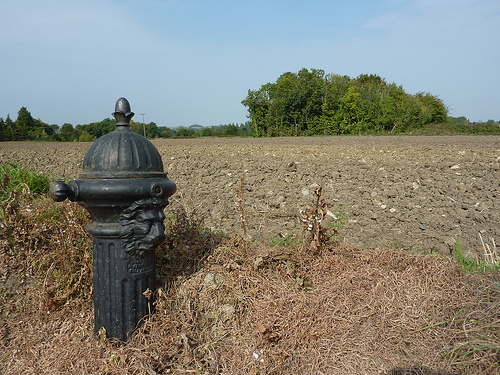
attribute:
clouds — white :
[33, 14, 153, 72]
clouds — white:
[101, 46, 232, 104]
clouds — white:
[328, 16, 419, 58]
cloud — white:
[7, 12, 197, 72]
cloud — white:
[297, 8, 447, 53]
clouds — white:
[383, 11, 424, 51]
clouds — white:
[330, 19, 373, 56]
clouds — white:
[232, 17, 288, 63]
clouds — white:
[448, 13, 481, 56]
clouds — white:
[308, 18, 343, 58]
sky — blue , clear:
[3, 1, 491, 118]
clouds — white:
[2, 2, 202, 77]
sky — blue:
[0, 0, 490, 65]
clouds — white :
[4, 5, 170, 82]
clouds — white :
[362, 3, 497, 68]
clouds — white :
[175, 25, 361, 73]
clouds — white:
[364, 15, 449, 65]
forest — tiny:
[273, 130, 343, 192]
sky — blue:
[434, 12, 494, 96]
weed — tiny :
[299, 185, 338, 248]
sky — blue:
[191, 31, 256, 74]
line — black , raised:
[121, 132, 138, 171]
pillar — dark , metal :
[51, 97, 178, 340]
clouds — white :
[10, 11, 478, 88]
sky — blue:
[40, 21, 247, 88]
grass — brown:
[0, 171, 498, 372]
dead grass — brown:
[2, 201, 497, 372]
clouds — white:
[66, 15, 138, 75]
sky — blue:
[205, 7, 402, 61]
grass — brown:
[2, 154, 62, 206]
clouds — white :
[127, 30, 290, 70]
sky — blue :
[0, 0, 499, 128]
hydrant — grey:
[62, 95, 233, 328]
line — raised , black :
[110, 131, 124, 173]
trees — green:
[234, 62, 456, 157]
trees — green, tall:
[240, 70, 449, 135]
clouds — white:
[5, 2, 495, 128]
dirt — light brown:
[0, 139, 498, 257]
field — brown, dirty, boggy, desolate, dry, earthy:
[236, 150, 398, 242]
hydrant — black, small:
[46, 98, 175, 344]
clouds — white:
[124, 68, 200, 111]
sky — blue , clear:
[1, 2, 497, 141]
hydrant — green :
[53, 94, 179, 346]